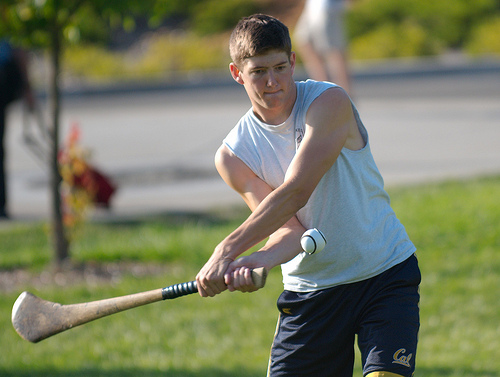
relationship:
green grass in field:
[424, 239, 478, 327] [3, 176, 497, 373]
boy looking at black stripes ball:
[193, 10, 423, 377] [299, 227, 328, 257]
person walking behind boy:
[290, 1, 350, 98] [193, 10, 423, 374]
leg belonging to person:
[290, 10, 328, 81] [290, 1, 350, 98]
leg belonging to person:
[306, 2, 351, 94] [290, 1, 350, 98]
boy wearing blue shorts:
[193, 10, 423, 374] [265, 255, 424, 376]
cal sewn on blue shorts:
[391, 348, 413, 367] [265, 255, 424, 376]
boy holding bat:
[193, 10, 423, 374] [10, 265, 268, 345]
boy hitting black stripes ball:
[193, 10, 423, 377] [299, 227, 328, 257]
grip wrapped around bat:
[162, 279, 196, 300] [9, 266, 267, 344]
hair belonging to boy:
[228, 9, 293, 74] [193, 10, 423, 377]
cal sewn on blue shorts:
[391, 344, 411, 365] [265, 255, 424, 376]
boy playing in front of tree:
[193, 10, 423, 374] [1, 0, 175, 270]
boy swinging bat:
[193, 10, 423, 377] [9, 266, 267, 344]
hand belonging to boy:
[193, 255, 233, 299] [193, 10, 423, 377]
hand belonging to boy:
[221, 253, 268, 293] [193, 10, 423, 377]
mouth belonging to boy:
[260, 86, 282, 96] [193, 10, 423, 377]